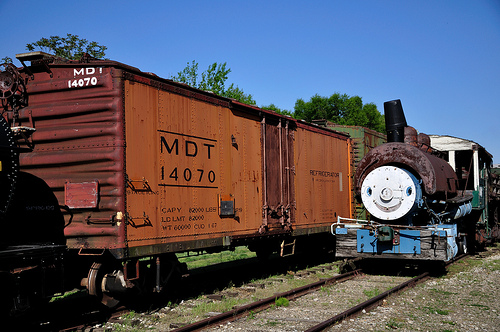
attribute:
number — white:
[65, 76, 100, 88]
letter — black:
[184, 134, 201, 158]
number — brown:
[165, 162, 184, 184]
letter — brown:
[201, 140, 222, 167]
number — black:
[181, 165, 193, 181]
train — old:
[331, 100, 496, 274]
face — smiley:
[348, 157, 423, 224]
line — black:
[154, 181, 217, 189]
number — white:
[89, 74, 97, 87]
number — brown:
[195, 165, 204, 185]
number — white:
[66, 77, 96, 91]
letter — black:
[154, 135, 189, 162]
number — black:
[167, 165, 179, 182]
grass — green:
[275, 293, 290, 309]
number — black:
[158, 163, 167, 184]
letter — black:
[156, 134, 183, 155]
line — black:
[155, 117, 222, 138]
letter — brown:
[158, 134, 179, 158]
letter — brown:
[182, 139, 199, 157]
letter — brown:
[200, 141, 212, 160]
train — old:
[1, 45, 392, 312]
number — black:
[199, 162, 219, 194]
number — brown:
[136, 127, 246, 201]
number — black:
[194, 165, 205, 184]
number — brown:
[206, 167, 216, 183]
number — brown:
[166, 167, 187, 185]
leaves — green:
[288, 94, 385, 128]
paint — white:
[370, 169, 403, 184]